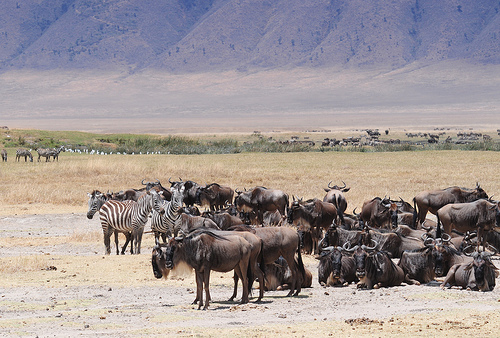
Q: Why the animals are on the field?
A: Resting.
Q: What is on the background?
A: Mountain.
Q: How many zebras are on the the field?
A: Three.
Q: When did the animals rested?
A: This morning.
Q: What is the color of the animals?
A: Brown.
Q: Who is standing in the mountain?
A: No one.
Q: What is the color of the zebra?
A: Black and white.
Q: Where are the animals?
A: In the field.